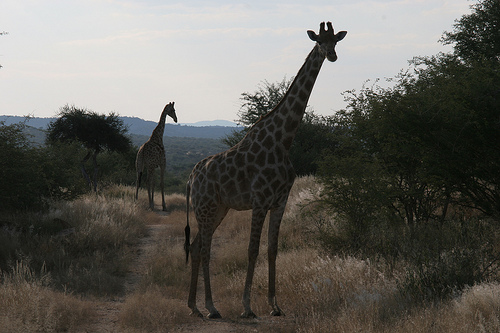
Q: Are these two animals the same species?
A: Yes, all the animals are giraffes.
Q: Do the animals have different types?
A: No, all the animals are giraffes.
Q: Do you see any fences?
A: No, there are no fences.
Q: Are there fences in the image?
A: No, there are no fences.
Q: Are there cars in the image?
A: No, there are no cars.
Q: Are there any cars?
A: No, there are no cars.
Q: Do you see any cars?
A: No, there are no cars.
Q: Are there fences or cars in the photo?
A: No, there are no cars or fences.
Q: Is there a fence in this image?
A: No, there are no fences.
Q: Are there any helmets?
A: No, there are no helmets.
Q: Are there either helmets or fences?
A: No, there are no helmets or fences.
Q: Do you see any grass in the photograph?
A: Yes, there is grass.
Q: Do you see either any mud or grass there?
A: Yes, there is grass.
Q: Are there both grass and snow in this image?
A: No, there is grass but no snow.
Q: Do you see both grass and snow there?
A: No, there is grass but no snow.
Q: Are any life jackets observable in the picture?
A: No, there are no life jackets.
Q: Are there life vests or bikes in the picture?
A: No, there are no life vests or bikes.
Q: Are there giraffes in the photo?
A: Yes, there is a giraffe.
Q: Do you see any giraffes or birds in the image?
A: Yes, there is a giraffe.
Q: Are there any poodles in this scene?
A: No, there are no poodles.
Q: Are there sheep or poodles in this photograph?
A: No, there are no poodles or sheep.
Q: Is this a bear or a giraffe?
A: This is a giraffe.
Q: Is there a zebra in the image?
A: No, there are no zebras.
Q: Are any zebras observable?
A: No, there are no zebras.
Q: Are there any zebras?
A: No, there are no zebras.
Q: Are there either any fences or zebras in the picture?
A: No, there are no zebras or fences.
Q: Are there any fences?
A: No, there are no fences.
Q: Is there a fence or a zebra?
A: No, there are no fences or zebras.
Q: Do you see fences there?
A: No, there are no fences.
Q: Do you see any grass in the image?
A: Yes, there is grass.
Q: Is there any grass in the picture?
A: Yes, there is grass.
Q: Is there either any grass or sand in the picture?
A: Yes, there is grass.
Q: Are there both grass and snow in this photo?
A: No, there is grass but no snow.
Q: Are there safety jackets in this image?
A: No, there are no safety jackets.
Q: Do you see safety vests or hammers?
A: No, there are no safety vests or hammers.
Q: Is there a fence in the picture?
A: No, there are no fences.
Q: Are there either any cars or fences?
A: No, there are no fences or cars.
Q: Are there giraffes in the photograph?
A: Yes, there is a giraffe.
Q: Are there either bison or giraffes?
A: Yes, there is a giraffe.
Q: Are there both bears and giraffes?
A: No, there is a giraffe but no bears.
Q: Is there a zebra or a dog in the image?
A: No, there are no zebras or dogs.